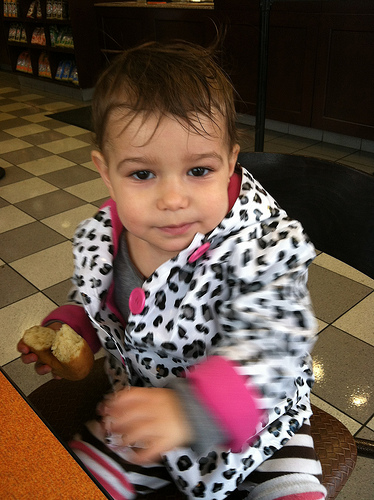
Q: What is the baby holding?
A: A donut.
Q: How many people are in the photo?
A: One.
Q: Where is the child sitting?
A: In a chair.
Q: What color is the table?
A: Brown.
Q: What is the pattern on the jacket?
A: Leopard.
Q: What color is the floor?
A: Gray and white.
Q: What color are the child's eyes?
A: Brown.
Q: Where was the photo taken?
A: On the floor.